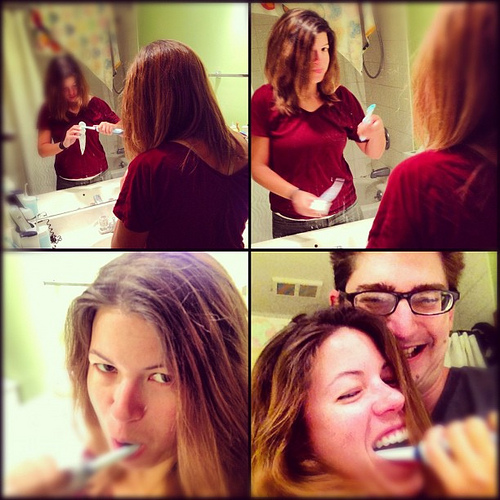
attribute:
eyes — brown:
[93, 358, 171, 387]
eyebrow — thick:
[353, 280, 397, 296]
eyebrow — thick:
[408, 282, 449, 293]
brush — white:
[59, 443, 141, 492]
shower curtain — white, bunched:
[445, 332, 485, 368]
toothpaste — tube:
[67, 114, 97, 154]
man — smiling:
[323, 249, 464, 384]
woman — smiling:
[252, 301, 462, 493]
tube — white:
[77, 117, 87, 157]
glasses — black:
[337, 282, 460, 322]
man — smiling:
[319, 247, 468, 392]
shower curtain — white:
[2, 7, 60, 195]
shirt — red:
[109, 140, 249, 249]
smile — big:
[395, 338, 430, 361]